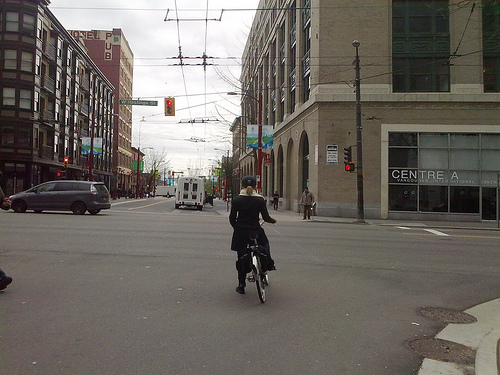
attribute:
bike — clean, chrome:
[237, 214, 270, 305]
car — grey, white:
[8, 178, 112, 214]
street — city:
[2, 200, 499, 373]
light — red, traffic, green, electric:
[166, 99, 177, 115]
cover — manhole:
[417, 304, 475, 326]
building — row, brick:
[0, 1, 113, 203]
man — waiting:
[298, 187, 316, 220]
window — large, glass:
[21, 51, 34, 74]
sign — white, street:
[246, 122, 260, 152]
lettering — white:
[390, 167, 461, 183]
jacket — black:
[228, 187, 275, 261]